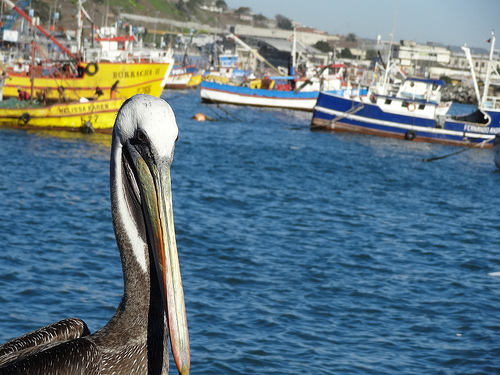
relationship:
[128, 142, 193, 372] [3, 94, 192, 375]
beak belonging to bird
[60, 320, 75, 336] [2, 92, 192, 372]
feather adorning bird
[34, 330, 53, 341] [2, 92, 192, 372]
feather adorning bird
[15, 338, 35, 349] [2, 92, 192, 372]
feather adorning bird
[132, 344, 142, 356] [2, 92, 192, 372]
feather adorning bird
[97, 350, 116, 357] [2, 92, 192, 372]
feather adorning bird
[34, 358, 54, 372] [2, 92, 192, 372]
feather belonging to bird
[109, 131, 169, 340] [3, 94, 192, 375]
neck belonging to bird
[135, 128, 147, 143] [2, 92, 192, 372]
eye belonging to bird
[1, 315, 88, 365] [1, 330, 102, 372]
wing tucked on top of back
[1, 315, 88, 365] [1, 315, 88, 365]
wing tucked on top of wing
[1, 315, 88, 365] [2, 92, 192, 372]
wing belonging to bird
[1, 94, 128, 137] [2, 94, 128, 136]
paint covering boat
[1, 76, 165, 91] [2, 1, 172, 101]
line painted on boat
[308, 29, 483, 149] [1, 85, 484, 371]
boat anchored in water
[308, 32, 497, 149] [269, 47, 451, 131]
boat on dock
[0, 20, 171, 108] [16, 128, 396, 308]
boat in water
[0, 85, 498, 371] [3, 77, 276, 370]
water behind bird